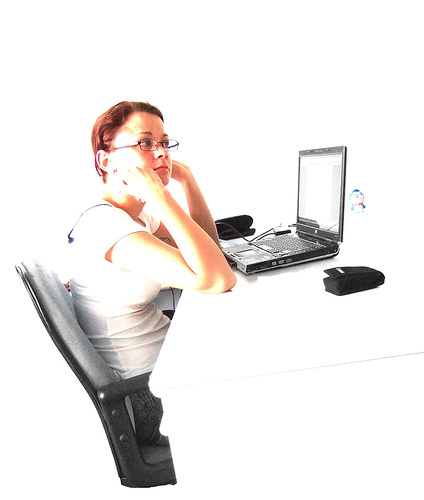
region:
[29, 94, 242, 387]
girl sitting at desk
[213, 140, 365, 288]
open laptop on desk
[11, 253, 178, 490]
office chair with black arms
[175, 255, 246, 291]
bent elbow on desk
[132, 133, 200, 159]
glasses on girl's face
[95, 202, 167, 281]
short sleeves on shirt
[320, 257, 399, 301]
black case on desk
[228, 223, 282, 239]
wires next to computer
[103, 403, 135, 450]
bolts on side of chair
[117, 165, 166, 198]
hand touching girl's face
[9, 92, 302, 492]
woman sitting at desk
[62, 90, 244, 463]
woman with short red hair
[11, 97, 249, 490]
woman sitting in grey and black chair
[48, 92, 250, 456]
woman wearing white shirt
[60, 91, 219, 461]
woman wearing glasses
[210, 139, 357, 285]
woman with black lap top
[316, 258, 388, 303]
black phone case on desk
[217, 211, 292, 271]
electrical cords connected to computer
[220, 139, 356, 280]
lap top shown open on desk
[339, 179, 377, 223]
small white and black penguin in background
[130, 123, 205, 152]
glasses on woman's face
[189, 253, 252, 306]
woman's shoulders on white table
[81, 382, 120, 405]
large black screw in chair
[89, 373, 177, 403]
black handle on chair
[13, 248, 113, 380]
gray pillow on chair back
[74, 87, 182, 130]
shiny red hair on woman's head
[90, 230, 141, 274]
red spot on woman's white shirt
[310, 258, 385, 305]
black wallet on white surface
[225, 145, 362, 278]
open black lap top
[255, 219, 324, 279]
black keys on lap top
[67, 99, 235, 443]
a woman wearing glasses is sitting at a desk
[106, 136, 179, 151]
a pair of perscription glasses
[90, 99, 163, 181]
this girl has short brown hair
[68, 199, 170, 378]
the girl is waering a white blouse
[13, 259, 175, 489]
the young woman is sitting on an office chair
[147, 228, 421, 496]
the young woman is resting her elbows on a white desk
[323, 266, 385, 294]
a black cell phone is on top of the white desk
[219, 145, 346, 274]
a laptop is on top of the white desk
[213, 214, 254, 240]
an open eye glass case is on top of the white desk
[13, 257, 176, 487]
the office chair has a grey padded cushion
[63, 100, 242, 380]
Girl sitting at computer.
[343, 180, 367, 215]
Picture of a snowman.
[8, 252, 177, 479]
Office chair she is sitting on.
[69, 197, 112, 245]
Ear buds hanging over her shoulder.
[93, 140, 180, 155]
Girl wearing glasses.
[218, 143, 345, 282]
Laptop on the table.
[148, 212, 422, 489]
Girl is sitting at a white desk.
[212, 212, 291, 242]
Electronic cords going to laptop.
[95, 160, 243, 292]
Girl is resting her elbows on the desk.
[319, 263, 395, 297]
Cellphone sitting on the desk.